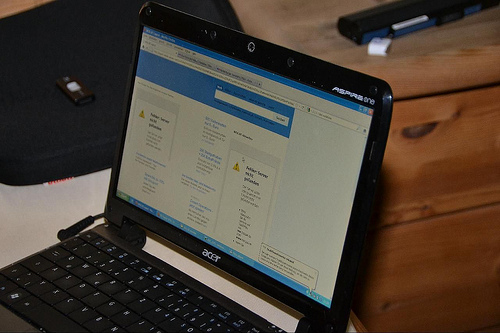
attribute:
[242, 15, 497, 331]
drawers — wooden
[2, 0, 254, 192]
case — black, laptop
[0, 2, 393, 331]
laptop — on, black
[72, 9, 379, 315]
laptop — open